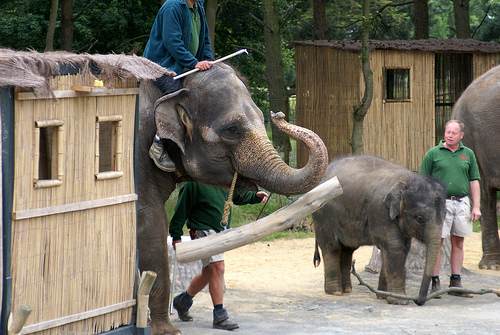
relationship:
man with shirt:
[410, 117, 484, 297] [422, 139, 479, 200]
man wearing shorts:
[410, 117, 484, 297] [440, 197, 474, 239]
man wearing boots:
[410, 117, 484, 297] [429, 274, 474, 299]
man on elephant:
[141, 0, 211, 176] [102, 35, 322, 330]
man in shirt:
[410, 117, 484, 297] [415, 138, 480, 203]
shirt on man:
[419, 141, 483, 199] [410, 117, 484, 297]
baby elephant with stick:
[315, 155, 446, 305] [352, 262, 499, 312]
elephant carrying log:
[128, 62, 330, 332] [207, 196, 391, 218]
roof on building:
[289, 35, 498, 53] [298, 39, 498, 169]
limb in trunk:
[334, 272, 497, 307] [413, 224, 438, 304]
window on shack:
[31, 115, 68, 191] [14, 84, 136, 297]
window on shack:
[87, 109, 122, 180] [14, 84, 136, 297]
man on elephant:
[141, 0, 211, 176] [128, 62, 330, 332]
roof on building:
[287, 32, 490, 47] [288, 27, 497, 194]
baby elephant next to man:
[315, 155, 446, 305] [410, 117, 484, 297]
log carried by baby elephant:
[172, 176, 340, 263] [315, 155, 446, 305]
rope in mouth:
[221, 169, 237, 229] [231, 170, 262, 192]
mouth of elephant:
[231, 170, 262, 192] [128, 62, 330, 332]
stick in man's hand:
[159, 34, 260, 94] [250, 188, 270, 205]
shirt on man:
[410, 129, 484, 197] [416, 118, 486, 304]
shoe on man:
[426, 270, 446, 304] [408, 113, 490, 308]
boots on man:
[448, 276, 471, 298] [408, 113, 490, 308]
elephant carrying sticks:
[130, 62, 329, 333] [169, 168, 344, 273]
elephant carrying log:
[130, 62, 329, 333] [192, 209, 296, 255]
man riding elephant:
[141, 0, 211, 176] [128, 62, 330, 332]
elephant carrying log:
[128, 62, 330, 332] [165, 168, 355, 272]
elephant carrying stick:
[130, 62, 329, 333] [202, 154, 254, 246]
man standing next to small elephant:
[410, 117, 484, 297] [308, 147, 448, 297]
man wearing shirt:
[410, 117, 484, 297] [411, 132, 484, 203]